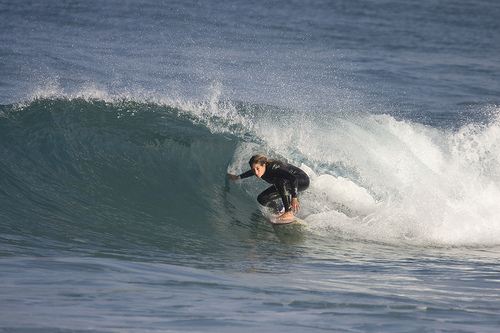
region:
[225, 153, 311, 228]
woman surfer in black wetsuit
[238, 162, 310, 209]
shiny wet black neoprene wetsuit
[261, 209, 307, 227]
white surfboard on a wave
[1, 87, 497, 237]
breaking wave in the ocean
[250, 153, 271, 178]
surfer head with long hair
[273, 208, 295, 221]
woman's foot on white surfboard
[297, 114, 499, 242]
turbulent white water of breaking wave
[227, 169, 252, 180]
right arm in a black wetsuit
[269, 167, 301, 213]
left arm in a black wetsuit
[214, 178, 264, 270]
reflection of surfer in black wetsuit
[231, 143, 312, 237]
a surfer riding a board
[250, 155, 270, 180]
the head of a surfer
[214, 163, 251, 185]
the arm of a surfer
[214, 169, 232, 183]
the hand of a surfer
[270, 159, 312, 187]
the torso of a surfer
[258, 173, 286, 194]
the thighs of a surfer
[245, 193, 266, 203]
the knee of a surfer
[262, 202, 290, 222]
the feet of a surfer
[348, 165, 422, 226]
the crashing of some waves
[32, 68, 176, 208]
a wave that is forming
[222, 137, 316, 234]
The woman is on a surfboard.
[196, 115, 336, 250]
The woman is wearing a wetsuit.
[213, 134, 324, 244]
The woman's wetsuit is black.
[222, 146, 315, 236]
The woman's hair is long.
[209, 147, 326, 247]
The woman's hair is in a ponytail.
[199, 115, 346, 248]
The surfboard is in the water.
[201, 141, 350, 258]
The wetsuit is wet.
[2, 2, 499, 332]
The water is blue and white.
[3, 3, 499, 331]
The water is splashing.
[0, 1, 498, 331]
The water is wavy.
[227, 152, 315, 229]
the woman is surfing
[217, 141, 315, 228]
woman is touching the water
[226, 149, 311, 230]
woman is wearing a wet suit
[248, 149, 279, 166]
woman's hair is wet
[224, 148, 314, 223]
woman is squatting down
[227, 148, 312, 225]
woman's wet suit is black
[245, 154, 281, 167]
woman's hair is blonde and brown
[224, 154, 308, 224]
woman is out in ocean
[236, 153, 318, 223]
woman's wet suit is wet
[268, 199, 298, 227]
woman has no shoes on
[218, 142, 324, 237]
A woman surfing a wave